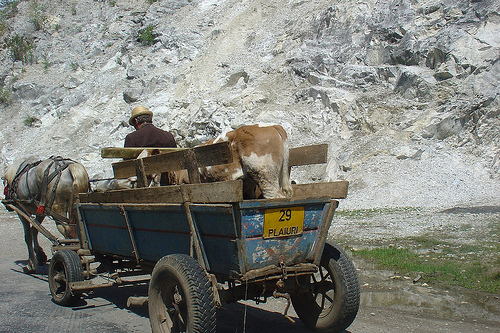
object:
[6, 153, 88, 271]
horse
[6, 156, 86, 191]
harness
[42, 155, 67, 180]
straps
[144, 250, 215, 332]
wheel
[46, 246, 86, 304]
wheel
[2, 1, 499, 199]
hillside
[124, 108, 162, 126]
hat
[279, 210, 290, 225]
29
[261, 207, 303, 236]
license plate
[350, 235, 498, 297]
grass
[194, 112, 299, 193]
cow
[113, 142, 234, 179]
wood plank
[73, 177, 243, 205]
wood plank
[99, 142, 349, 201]
fence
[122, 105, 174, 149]
man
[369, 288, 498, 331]
dirt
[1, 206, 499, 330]
road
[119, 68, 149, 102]
rocks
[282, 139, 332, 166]
wood plank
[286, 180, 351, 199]
wood plank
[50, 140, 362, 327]
carriage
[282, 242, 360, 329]
wheel